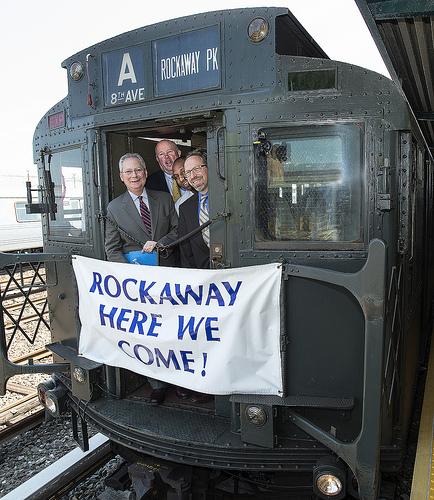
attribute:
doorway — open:
[100, 122, 221, 418]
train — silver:
[24, 6, 433, 499]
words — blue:
[86, 272, 244, 379]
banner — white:
[69, 253, 287, 398]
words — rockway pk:
[158, 45, 218, 83]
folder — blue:
[123, 249, 159, 267]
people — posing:
[104, 139, 216, 407]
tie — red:
[136, 196, 154, 236]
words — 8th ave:
[107, 87, 148, 104]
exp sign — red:
[47, 111, 68, 130]